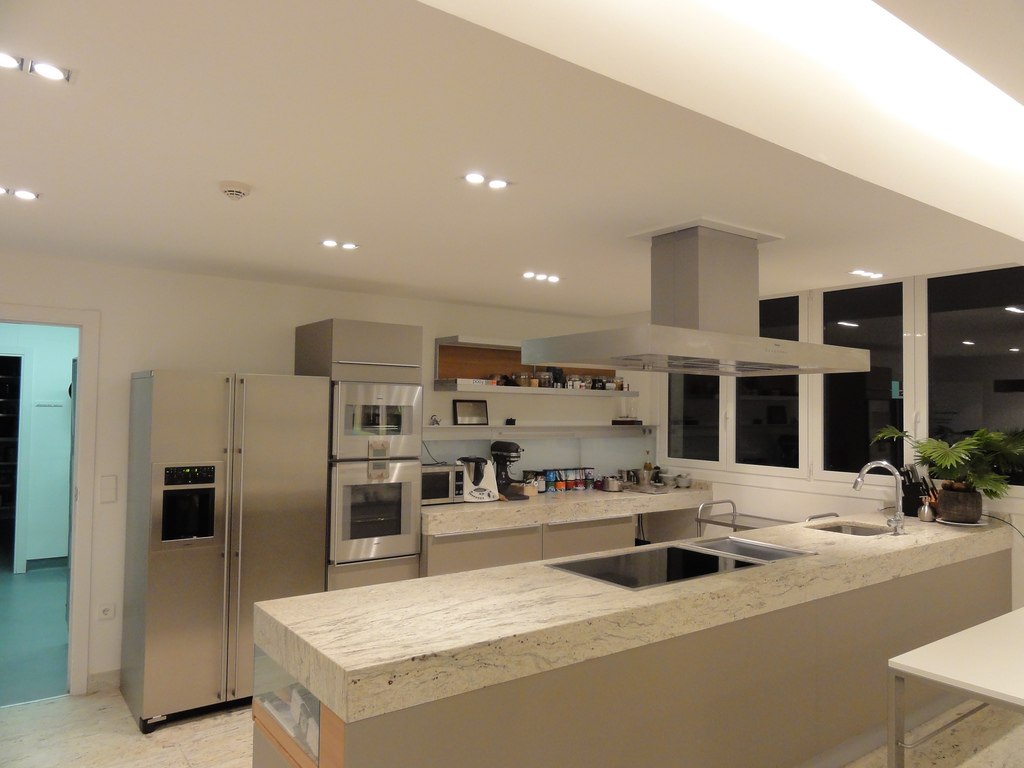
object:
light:
[465, 173, 508, 190]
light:
[523, 271, 559, 283]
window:
[665, 371, 720, 466]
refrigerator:
[115, 369, 329, 732]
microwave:
[419, 462, 465, 506]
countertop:
[422, 482, 713, 538]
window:
[928, 269, 1024, 485]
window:
[819, 269, 902, 467]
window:
[733, 295, 801, 469]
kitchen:
[0, 0, 1024, 768]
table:
[887, 599, 1024, 767]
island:
[249, 506, 1011, 768]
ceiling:
[419, 104, 556, 236]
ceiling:
[492, 232, 609, 319]